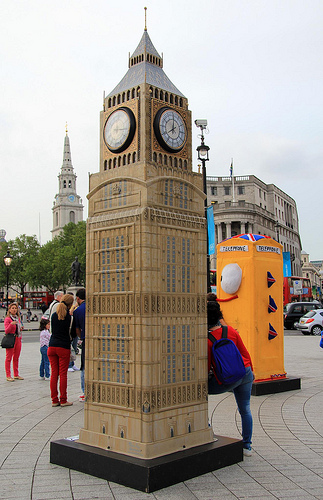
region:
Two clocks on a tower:
[91, 96, 194, 164]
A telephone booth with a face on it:
[209, 222, 297, 400]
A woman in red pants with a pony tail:
[39, 287, 81, 413]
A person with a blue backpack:
[194, 292, 262, 460]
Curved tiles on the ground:
[265, 410, 321, 498]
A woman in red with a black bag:
[3, 295, 26, 384]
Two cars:
[284, 294, 322, 335]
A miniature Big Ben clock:
[62, 39, 242, 485]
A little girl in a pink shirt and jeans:
[28, 313, 60, 378]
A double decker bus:
[18, 285, 54, 312]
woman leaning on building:
[183, 294, 273, 461]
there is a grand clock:
[46, 7, 246, 491]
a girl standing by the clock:
[205, 286, 254, 458]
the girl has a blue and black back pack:
[203, 324, 247, 384]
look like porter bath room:
[210, 234, 297, 393]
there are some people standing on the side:
[1, 286, 88, 410]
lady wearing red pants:
[43, 347, 71, 404]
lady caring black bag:
[0, 314, 20, 350]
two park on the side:
[283, 296, 322, 337]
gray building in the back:
[0, 114, 320, 320]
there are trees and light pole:
[0, 216, 85, 320]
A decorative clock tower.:
[52, 11, 245, 489]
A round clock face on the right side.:
[151, 102, 188, 153]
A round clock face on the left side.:
[97, 104, 137, 150]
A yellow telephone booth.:
[213, 226, 308, 395]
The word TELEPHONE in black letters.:
[219, 244, 253, 255]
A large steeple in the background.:
[50, 116, 88, 229]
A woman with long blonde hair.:
[50, 293, 78, 329]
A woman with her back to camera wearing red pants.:
[43, 339, 81, 416]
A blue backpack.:
[207, 324, 256, 395]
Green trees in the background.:
[21, 233, 82, 288]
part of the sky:
[227, 61, 271, 107]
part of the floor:
[275, 432, 306, 482]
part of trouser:
[236, 408, 252, 440]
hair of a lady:
[56, 304, 64, 315]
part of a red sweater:
[222, 323, 243, 349]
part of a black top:
[50, 330, 64, 353]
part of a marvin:
[208, 307, 218, 318]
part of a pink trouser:
[7, 354, 18, 365]